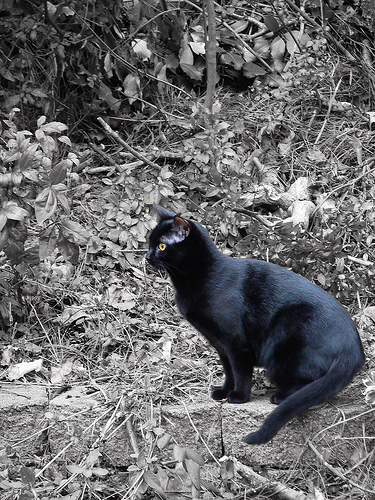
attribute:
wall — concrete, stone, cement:
[2, 376, 374, 489]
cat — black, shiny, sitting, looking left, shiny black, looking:
[138, 200, 368, 450]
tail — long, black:
[238, 349, 355, 455]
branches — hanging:
[116, 396, 142, 460]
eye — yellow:
[154, 240, 167, 252]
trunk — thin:
[200, 1, 224, 110]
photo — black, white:
[1, 1, 371, 498]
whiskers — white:
[151, 255, 181, 276]